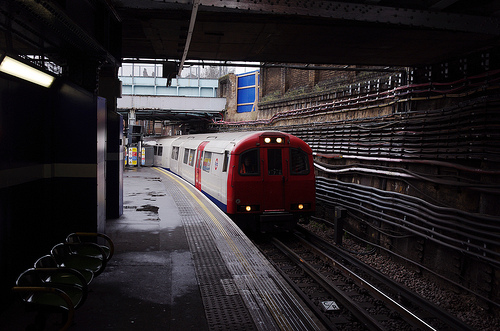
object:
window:
[265, 145, 283, 176]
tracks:
[257, 218, 499, 329]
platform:
[89, 165, 319, 330]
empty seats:
[62, 231, 117, 264]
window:
[238, 146, 264, 178]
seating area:
[0, 220, 122, 329]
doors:
[195, 144, 203, 186]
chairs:
[9, 265, 91, 331]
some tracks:
[262, 227, 439, 330]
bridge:
[114, 60, 228, 118]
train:
[152, 129, 318, 237]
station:
[0, 0, 500, 330]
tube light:
[0, 52, 57, 90]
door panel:
[191, 141, 206, 192]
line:
[152, 165, 293, 330]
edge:
[152, 165, 331, 330]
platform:
[44, 163, 332, 327]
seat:
[48, 237, 115, 274]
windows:
[181, 147, 192, 166]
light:
[296, 202, 306, 210]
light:
[244, 205, 254, 213]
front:
[226, 130, 318, 217]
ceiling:
[105, 0, 500, 67]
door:
[261, 146, 289, 211]